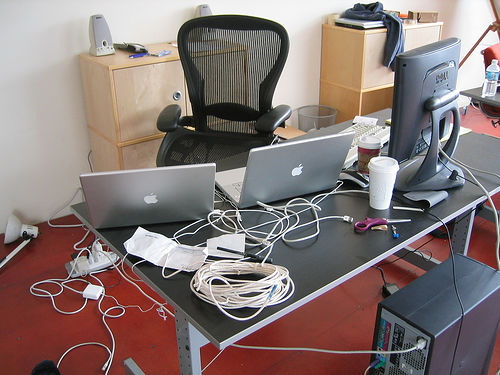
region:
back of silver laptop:
[67, 155, 217, 218]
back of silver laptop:
[240, 136, 349, 203]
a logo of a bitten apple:
[138, 187, 163, 206]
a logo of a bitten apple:
[288, 159, 310, 180]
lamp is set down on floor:
[0, 214, 40, 277]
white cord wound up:
[198, 257, 298, 310]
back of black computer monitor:
[396, 51, 487, 169]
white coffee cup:
[356, 152, 406, 208]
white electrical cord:
[44, 268, 127, 373]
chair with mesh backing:
[177, 24, 278, 134]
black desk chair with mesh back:
[153, 11, 293, 175]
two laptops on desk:
[68, 128, 360, 230]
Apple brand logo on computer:
[139, 189, 161, 206]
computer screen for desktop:
[386, 35, 468, 194]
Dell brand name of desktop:
[431, 68, 453, 85]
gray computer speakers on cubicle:
[87, 2, 224, 59]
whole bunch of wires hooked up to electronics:
[26, 133, 498, 373]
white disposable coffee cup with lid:
[366, 151, 402, 212]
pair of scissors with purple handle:
[351, 216, 416, 234]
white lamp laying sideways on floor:
[0, 208, 42, 283]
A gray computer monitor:
[393, 44, 478, 184]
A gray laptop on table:
[225, 122, 345, 197]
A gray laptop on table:
[78, 156, 224, 244]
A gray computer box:
[365, 239, 497, 366]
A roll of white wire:
[186, 255, 291, 312]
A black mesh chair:
[146, 5, 296, 157]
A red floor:
[10, 299, 46, 353]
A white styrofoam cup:
[359, 148, 402, 217]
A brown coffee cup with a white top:
[356, 126, 388, 173]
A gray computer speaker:
[82, 11, 118, 60]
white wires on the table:
[139, 198, 294, 329]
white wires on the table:
[177, 229, 320, 341]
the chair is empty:
[137, 15, 313, 220]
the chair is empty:
[165, 22, 383, 287]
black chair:
[148, 4, 297, 162]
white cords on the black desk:
[135, 177, 348, 337]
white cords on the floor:
[37, 246, 166, 373]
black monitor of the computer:
[381, 41, 482, 204]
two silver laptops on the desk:
[65, 127, 351, 228]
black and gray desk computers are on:
[66, 92, 498, 357]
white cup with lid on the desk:
[366, 152, 395, 212]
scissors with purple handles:
[353, 211, 414, 233]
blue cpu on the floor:
[358, 241, 498, 370]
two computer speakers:
[83, 12, 228, 47]